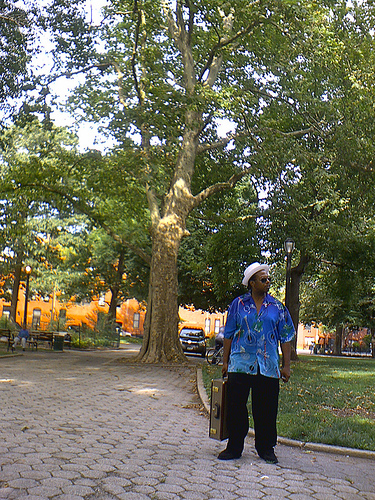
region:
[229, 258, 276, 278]
Man is wearing a white hat.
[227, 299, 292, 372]
Man is wearing a colorful blue shirt.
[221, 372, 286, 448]
Man is wearing black pants.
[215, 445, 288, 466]
Man is wearing black sneakers.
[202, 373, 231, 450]
Heavy briefcase in man's hand.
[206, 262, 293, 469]
Man carrying a briefcase.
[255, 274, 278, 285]
Man's sunglasses are black.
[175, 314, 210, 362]
Black car parked by tree.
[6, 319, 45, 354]
A man sits on the bench in the park.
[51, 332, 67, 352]
Green garbage can next to bench.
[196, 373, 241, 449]
A man is carrying a suitcase.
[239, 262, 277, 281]
The man is wearing a white hat.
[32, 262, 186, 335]
The orange building in the background.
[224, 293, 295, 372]
The shirt is blue.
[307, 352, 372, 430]
The grass is green.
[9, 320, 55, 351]
A person sitting on the bench.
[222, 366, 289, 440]
The man is wearing black pants.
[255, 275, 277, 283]
The man is wearing sunglasses.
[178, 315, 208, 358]
A car is parked on the curve.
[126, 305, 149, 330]
The building has windows.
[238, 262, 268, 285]
the white hat the man is wearing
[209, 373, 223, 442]
the suitcase the man is holding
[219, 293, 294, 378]
the blue shirt the man is holding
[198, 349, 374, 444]
the green grass of the park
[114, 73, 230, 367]
a tall tree in the center of the park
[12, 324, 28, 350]
a man sitting on the bench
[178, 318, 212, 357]
a car sitting by the park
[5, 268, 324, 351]
some buildings by the park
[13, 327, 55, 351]
a bench in the park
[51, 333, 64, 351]
a trash can next to the bench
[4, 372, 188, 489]
pavement made of cement tile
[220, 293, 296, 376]
shirt the gentleman is weariing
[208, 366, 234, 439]
suitcase man is holding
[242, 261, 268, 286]
hat the gentleman has on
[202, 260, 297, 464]
man waiting for a bus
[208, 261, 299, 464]
guy traveling to the bus stop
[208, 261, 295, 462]
salesman ready to hussle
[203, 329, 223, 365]
a guy trying to repair his bike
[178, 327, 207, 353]
parked car on the sidewalk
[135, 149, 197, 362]
large tree in the middle of a park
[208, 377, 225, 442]
brown square suit case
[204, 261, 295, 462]
man standing on the side of street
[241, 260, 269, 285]
white hat on man's head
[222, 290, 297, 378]
blue shirt with designs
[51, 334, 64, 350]
green trash can in the park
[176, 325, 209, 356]
truck parked next to the curb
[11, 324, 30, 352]
man sitting on a bench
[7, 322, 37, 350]
man sitting on a wooden bench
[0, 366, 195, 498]
stone pavement on the road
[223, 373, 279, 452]
black slacks on the man